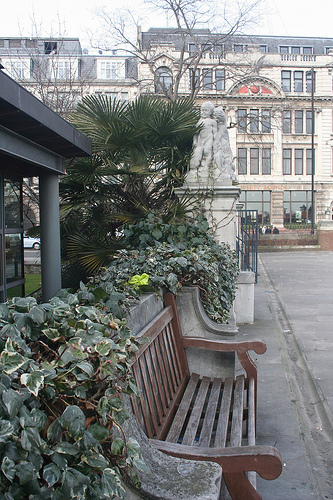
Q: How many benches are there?
A: One.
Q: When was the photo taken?
A: During the day.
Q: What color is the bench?
A: Brown.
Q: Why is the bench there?
A: So people can sit down.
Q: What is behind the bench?
A: A plant.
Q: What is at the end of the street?
A: A building.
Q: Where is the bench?
A: On the sidewalk.